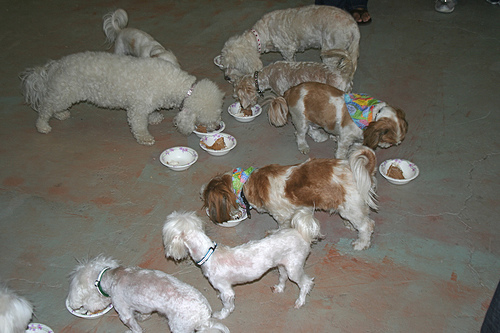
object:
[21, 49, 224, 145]
pet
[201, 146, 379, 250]
pet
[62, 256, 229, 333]
pet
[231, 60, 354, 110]
pet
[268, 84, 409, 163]
pet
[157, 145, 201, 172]
dish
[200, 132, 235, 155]
dish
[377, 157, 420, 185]
dish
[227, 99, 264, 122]
dish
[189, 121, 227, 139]
dish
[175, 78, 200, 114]
collar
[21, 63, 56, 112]
tail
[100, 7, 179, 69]
pet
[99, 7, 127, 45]
tail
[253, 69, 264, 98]
collar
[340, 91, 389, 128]
scarf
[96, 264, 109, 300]
collar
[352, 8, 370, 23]
foot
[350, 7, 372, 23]
sandal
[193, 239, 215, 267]
collar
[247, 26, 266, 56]
collar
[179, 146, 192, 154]
purple flowers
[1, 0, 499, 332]
floor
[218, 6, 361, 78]
pet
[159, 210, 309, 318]
pet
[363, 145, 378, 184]
spot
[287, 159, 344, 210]
spot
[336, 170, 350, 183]
spot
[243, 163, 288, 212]
spot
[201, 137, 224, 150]
food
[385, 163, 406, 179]
food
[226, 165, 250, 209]
bandana